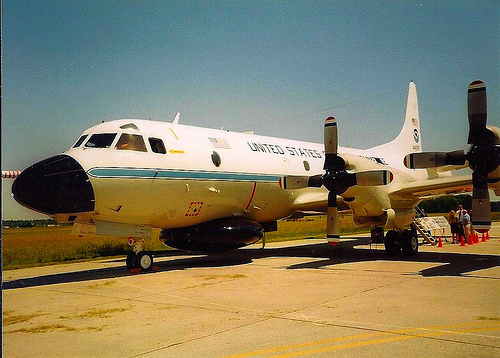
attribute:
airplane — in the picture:
[7, 79, 498, 273]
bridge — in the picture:
[414, 220, 434, 243]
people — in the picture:
[449, 195, 474, 244]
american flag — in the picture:
[206, 132, 236, 153]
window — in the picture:
[66, 129, 119, 149]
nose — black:
[23, 150, 90, 209]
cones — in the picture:
[435, 231, 489, 246]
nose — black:
[10, 154, 96, 216]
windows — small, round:
[207, 150, 224, 169]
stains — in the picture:
[1, 287, 150, 357]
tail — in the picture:
[393, 78, 433, 225]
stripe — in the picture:
[91, 162, 281, 185]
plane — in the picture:
[73, 67, 399, 266]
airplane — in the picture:
[12, 90, 474, 237]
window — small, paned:
[114, 131, 146, 151]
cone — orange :
[431, 230, 447, 250]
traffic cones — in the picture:
[455, 232, 491, 244]